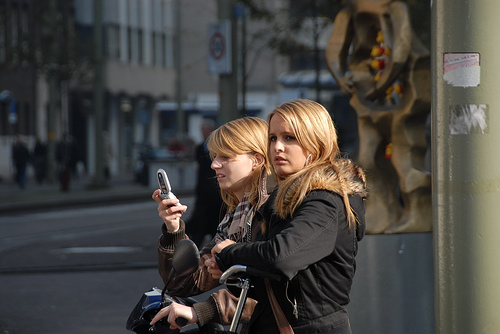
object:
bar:
[219, 264, 280, 334]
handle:
[245, 265, 281, 282]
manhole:
[62, 245, 141, 253]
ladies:
[207, 99, 367, 333]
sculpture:
[310, 1, 433, 235]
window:
[128, 0, 145, 69]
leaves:
[285, 67, 299, 74]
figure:
[324, 1, 432, 236]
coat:
[221, 157, 370, 333]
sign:
[205, 19, 232, 76]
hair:
[265, 98, 362, 230]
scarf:
[212, 185, 252, 242]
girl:
[152, 99, 367, 333]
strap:
[250, 218, 298, 334]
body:
[203, 99, 360, 333]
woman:
[152, 117, 267, 296]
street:
[0, 175, 499, 333]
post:
[431, 0, 500, 333]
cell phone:
[156, 168, 187, 215]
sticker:
[442, 51, 488, 136]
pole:
[433, 0, 500, 334]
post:
[213, 0, 246, 130]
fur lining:
[270, 156, 368, 219]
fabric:
[215, 190, 255, 245]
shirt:
[213, 191, 252, 244]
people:
[9, 133, 87, 192]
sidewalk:
[0, 158, 195, 332]